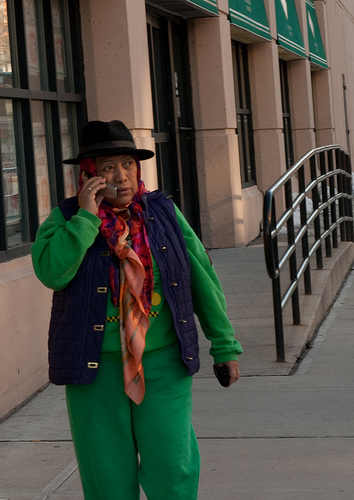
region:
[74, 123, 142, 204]
Woman talking on cell phone.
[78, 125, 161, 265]
Woman wearing scarf on her head under hat.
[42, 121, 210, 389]
Woman wearing unbuttoned blue vest.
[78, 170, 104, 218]
Ring on womans ring finger.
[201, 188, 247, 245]
Shadow of railing on building.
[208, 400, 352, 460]
Crack in sidewalk.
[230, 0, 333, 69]
Green awnings above windows.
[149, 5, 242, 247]
Entrance to building.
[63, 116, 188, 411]
Woman wearing long scarf.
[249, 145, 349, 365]
Black railing on ramp.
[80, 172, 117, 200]
a cellphone being held by a woman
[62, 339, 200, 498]
green pair of pants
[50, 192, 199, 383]
blue jacket being wore by a woman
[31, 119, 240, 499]
a woman with a hat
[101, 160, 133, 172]
the eyes of a woman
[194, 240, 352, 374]
a ramp to the door of a building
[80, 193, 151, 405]
pink scarf being wore by a woman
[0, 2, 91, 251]
set of windows behind a woman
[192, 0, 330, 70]
green signs on the side of the building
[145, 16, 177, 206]
the door of the building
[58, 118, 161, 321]
the woman on the phone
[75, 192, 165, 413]
the woman is wearing scarf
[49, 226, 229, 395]
the woman is wearing a vest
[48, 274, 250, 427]
the vest is purple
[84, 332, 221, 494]
woman wearing a green pants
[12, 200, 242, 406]
the jacket is green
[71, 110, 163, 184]
the woman is wearing a hat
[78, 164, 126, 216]
the phone is silver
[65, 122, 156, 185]
the hat is black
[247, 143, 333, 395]
the railings are black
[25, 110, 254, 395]
The woman is wearing a hat.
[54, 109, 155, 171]
The hat is black.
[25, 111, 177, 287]
The woman is holding a cell phone.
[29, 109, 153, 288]
The woman is wearing a ring.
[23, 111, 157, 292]
The ring is on the right hand.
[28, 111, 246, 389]
The woman is wearing a green shirt.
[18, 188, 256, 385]
The shirt has long sleeves.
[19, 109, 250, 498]
The woman is wearing pants.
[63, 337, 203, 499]
The pants are green.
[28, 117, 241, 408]
The woman is wearing a scarf.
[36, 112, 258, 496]
The woman is walking down the street.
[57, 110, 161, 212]
The woman is wearing a black hat.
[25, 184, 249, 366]
The woman is wearing a blue sweat shirt.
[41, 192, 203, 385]
The woman is wearing a blue vest.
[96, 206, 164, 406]
The woman is wearing a scarf.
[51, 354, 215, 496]
The woman is wearing green sweat pants.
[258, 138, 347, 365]
A black railing in the background.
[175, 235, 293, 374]
A ramp next to the black railing.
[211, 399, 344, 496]
Concrete on the sidewalk.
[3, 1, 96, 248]
A window on the building.